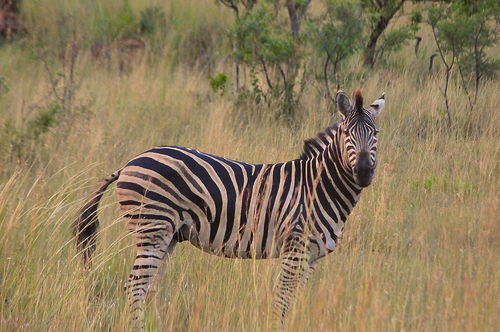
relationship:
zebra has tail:
[66, 80, 398, 331] [65, 163, 127, 266]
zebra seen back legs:
[66, 80, 398, 331] [113, 236, 177, 326]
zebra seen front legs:
[66, 80, 398, 331] [267, 255, 317, 332]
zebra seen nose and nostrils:
[66, 80, 398, 331] [351, 162, 381, 177]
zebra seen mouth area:
[66, 80, 398, 331] [346, 151, 378, 191]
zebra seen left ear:
[66, 80, 398, 331] [369, 89, 394, 119]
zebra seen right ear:
[66, 80, 398, 331] [333, 87, 355, 118]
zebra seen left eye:
[71, 88, 391, 331] [370, 127, 386, 139]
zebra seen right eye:
[66, 80, 398, 331] [342, 127, 353, 142]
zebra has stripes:
[66, 80, 398, 331] [114, 132, 353, 276]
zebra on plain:
[66, 80, 398, 331] [1, 3, 499, 326]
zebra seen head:
[66, 80, 398, 331] [327, 82, 394, 198]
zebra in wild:
[66, 80, 398, 331] [1, 3, 499, 326]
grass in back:
[1, 41, 496, 326] [5, 4, 70, 327]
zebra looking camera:
[66, 80, 398, 331] [407, 161, 488, 242]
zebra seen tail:
[66, 80, 398, 331] [65, 163, 127, 266]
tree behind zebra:
[215, 1, 408, 74] [66, 80, 398, 331]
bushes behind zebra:
[4, 7, 492, 98] [66, 80, 398, 331]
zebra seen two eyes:
[66, 80, 398, 331] [339, 126, 384, 139]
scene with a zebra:
[1, 3, 499, 326] [66, 80, 398, 331]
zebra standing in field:
[66, 80, 398, 331] [1, 3, 499, 326]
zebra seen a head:
[66, 80, 398, 331] [327, 82, 394, 198]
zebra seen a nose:
[66, 80, 398, 331] [346, 151, 378, 191]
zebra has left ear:
[66, 80, 398, 331] [369, 89, 394, 119]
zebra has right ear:
[66, 80, 398, 331] [333, 87, 355, 118]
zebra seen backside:
[66, 80, 398, 331] [136, 130, 338, 176]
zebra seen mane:
[66, 80, 398, 331] [300, 117, 342, 159]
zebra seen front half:
[66, 80, 398, 331] [240, 83, 404, 318]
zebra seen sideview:
[66, 80, 398, 331] [321, 101, 363, 187]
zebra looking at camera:
[66, 80, 398, 331] [407, 161, 488, 242]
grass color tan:
[1, 41, 496, 326] [66, 80, 398, 331]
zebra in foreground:
[66, 80, 398, 331] [7, 102, 498, 331]